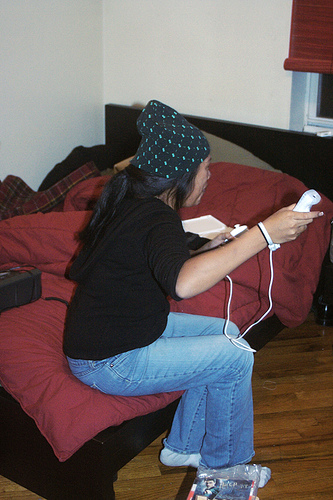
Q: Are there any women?
A: Yes, there is a woman.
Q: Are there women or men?
A: Yes, there is a woman.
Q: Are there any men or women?
A: Yes, there is a woman.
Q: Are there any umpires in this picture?
A: No, there are no umpires.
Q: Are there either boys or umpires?
A: No, there are no umpires or boys.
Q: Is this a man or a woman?
A: This is a woman.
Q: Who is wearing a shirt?
A: The woman is wearing a shirt.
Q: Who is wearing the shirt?
A: The woman is wearing a shirt.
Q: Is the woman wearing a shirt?
A: Yes, the woman is wearing a shirt.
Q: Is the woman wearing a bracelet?
A: No, the woman is wearing a shirt.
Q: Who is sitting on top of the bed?
A: The woman is sitting on top of the bed.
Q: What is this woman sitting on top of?
A: The woman is sitting on top of the bed.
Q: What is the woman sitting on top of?
A: The woman is sitting on top of the bed.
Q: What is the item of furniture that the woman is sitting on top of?
A: The piece of furniture is a bed.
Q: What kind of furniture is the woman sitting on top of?
A: The woman is sitting on top of the bed.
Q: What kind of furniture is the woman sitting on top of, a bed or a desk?
A: The woman is sitting on top of a bed.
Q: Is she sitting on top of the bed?
A: Yes, the woman is sitting on top of the bed.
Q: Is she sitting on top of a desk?
A: No, the woman is sitting on top of the bed.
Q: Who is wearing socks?
A: The woman is wearing socks.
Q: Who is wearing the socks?
A: The woman is wearing socks.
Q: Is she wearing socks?
A: Yes, the woman is wearing socks.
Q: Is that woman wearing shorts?
A: No, the woman is wearing socks.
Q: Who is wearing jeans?
A: The woman is wearing jeans.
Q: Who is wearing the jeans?
A: The woman is wearing jeans.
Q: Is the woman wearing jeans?
A: Yes, the woman is wearing jeans.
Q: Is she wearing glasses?
A: No, the woman is wearing jeans.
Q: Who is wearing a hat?
A: The woman is wearing a hat.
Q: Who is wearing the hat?
A: The woman is wearing a hat.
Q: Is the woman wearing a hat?
A: Yes, the woman is wearing a hat.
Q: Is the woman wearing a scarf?
A: No, the woman is wearing a hat.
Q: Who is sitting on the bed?
A: The woman is sitting on the bed.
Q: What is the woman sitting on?
A: The woman is sitting on the bed.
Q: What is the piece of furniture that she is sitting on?
A: The piece of furniture is a bed.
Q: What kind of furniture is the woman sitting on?
A: The woman is sitting on the bed.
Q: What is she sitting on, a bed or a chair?
A: The woman is sitting on a bed.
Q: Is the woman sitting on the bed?
A: Yes, the woman is sitting on the bed.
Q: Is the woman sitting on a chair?
A: No, the woman is sitting on the bed.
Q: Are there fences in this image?
A: No, there are no fences.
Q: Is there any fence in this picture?
A: No, there are no fences.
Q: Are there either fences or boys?
A: No, there are no fences or boys.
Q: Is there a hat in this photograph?
A: Yes, there is a hat.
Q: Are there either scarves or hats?
A: Yes, there is a hat.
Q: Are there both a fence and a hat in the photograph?
A: No, there is a hat but no fences.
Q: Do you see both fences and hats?
A: No, there is a hat but no fences.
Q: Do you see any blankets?
A: Yes, there is a blanket.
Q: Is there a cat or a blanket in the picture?
A: Yes, there is a blanket.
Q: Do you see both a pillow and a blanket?
A: Yes, there are both a blanket and a pillow.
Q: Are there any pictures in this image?
A: No, there are no pictures.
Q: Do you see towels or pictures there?
A: No, there are no pictures or towels.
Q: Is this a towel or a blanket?
A: This is a blanket.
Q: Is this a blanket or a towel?
A: This is a blanket.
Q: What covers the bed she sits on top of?
A: The blanket covers the bed.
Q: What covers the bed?
A: The blanket covers the bed.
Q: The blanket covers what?
A: The blanket covers the bed.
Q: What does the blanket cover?
A: The blanket covers the bed.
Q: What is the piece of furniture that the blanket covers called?
A: The piece of furniture is a bed.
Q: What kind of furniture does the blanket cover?
A: The blanket covers the bed.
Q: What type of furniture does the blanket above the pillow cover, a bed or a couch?
A: The blanket covers a bed.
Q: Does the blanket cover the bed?
A: Yes, the blanket covers the bed.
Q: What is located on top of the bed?
A: The blanket is on top of the bed.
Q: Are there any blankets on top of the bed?
A: Yes, there is a blanket on top of the bed.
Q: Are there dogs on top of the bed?
A: No, there is a blanket on top of the bed.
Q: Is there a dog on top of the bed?
A: No, there is a blanket on top of the bed.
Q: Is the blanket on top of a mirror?
A: No, the blanket is on top of the bed.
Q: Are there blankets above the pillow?
A: Yes, there is a blanket above the pillow.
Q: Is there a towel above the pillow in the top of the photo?
A: No, there is a blanket above the pillow.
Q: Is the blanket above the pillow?
A: Yes, the blanket is above the pillow.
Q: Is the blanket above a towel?
A: No, the blanket is above the pillow.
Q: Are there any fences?
A: No, there are no fences.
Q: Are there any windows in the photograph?
A: Yes, there is a window.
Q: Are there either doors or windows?
A: Yes, there is a window.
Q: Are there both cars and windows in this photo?
A: No, there is a window but no cars.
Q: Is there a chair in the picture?
A: No, there are no chairs.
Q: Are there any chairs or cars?
A: No, there are no chairs or cars.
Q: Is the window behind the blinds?
A: Yes, the window is behind the blinds.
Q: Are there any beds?
A: Yes, there is a bed.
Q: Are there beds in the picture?
A: Yes, there is a bed.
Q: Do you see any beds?
A: Yes, there is a bed.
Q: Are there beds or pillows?
A: Yes, there is a bed.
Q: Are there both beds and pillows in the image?
A: Yes, there are both a bed and a pillow.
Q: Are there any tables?
A: No, there are no tables.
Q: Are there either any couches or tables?
A: No, there are no tables or couches.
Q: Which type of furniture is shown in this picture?
A: The furniture is a bed.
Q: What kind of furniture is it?
A: The piece of furniture is a bed.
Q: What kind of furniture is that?
A: This is a bed.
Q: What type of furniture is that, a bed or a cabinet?
A: This is a bed.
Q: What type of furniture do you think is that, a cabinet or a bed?
A: This is a bed.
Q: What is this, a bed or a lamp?
A: This is a bed.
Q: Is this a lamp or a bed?
A: This is a bed.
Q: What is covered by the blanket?
A: The bed is covered by the blanket.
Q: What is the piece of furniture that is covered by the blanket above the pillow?
A: The piece of furniture is a bed.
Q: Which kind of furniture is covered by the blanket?
A: The piece of furniture is a bed.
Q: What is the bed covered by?
A: The bed is covered by the blanket.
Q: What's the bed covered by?
A: The bed is covered by the blanket.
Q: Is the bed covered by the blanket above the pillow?
A: Yes, the bed is covered by the blanket.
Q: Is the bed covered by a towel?
A: No, the bed is covered by the blanket.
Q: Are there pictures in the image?
A: No, there are no pictures.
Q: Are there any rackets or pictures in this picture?
A: No, there are no pictures or rackets.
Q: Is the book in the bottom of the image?
A: Yes, the book is in the bottom of the image.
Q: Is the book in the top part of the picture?
A: No, the book is in the bottom of the image.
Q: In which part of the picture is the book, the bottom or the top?
A: The book is in the bottom of the image.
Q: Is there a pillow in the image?
A: Yes, there is a pillow.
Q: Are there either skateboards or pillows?
A: Yes, there is a pillow.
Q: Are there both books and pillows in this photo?
A: Yes, there are both a pillow and a book.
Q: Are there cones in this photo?
A: No, there are no cones.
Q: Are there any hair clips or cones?
A: No, there are no cones or hair clips.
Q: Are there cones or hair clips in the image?
A: No, there are no cones or hair clips.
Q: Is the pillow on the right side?
A: Yes, the pillow is on the right of the image.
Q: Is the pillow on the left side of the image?
A: No, the pillow is on the right of the image.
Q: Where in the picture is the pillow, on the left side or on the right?
A: The pillow is on the right of the image.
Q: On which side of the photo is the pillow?
A: The pillow is on the right of the image.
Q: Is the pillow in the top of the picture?
A: Yes, the pillow is in the top of the image.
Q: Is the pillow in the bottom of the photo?
A: No, the pillow is in the top of the image.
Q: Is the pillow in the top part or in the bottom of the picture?
A: The pillow is in the top of the image.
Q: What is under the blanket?
A: The pillow is under the blanket.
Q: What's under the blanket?
A: The pillow is under the blanket.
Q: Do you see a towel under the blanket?
A: No, there is a pillow under the blanket.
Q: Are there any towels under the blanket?
A: No, there is a pillow under the blanket.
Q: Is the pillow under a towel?
A: No, the pillow is under the blanket.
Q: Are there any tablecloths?
A: No, there are no tablecloths.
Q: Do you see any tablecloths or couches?
A: No, there are no tablecloths or couches.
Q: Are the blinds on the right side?
A: Yes, the blinds are on the right of the image.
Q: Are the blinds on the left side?
A: No, the blinds are on the right of the image.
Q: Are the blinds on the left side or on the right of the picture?
A: The blinds are on the right of the image.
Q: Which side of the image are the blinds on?
A: The blinds are on the right of the image.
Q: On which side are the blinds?
A: The blinds are on the right of the image.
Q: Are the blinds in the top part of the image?
A: Yes, the blinds are in the top of the image.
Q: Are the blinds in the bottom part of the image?
A: No, the blinds are in the top of the image.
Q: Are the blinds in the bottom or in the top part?
A: The blinds are in the top of the image.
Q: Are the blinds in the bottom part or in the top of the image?
A: The blinds are in the top of the image.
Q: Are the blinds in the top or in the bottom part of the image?
A: The blinds are in the top of the image.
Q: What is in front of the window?
A: The blinds are in front of the window.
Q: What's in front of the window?
A: The blinds are in front of the window.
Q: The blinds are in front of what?
A: The blinds are in front of the window.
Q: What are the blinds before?
A: The blinds are in front of the window.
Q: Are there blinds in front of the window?
A: Yes, there are blinds in front of the window.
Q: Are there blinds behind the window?
A: No, the blinds are in front of the window.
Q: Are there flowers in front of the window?
A: No, there are blinds in front of the window.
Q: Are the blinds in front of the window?
A: Yes, the blinds are in front of the window.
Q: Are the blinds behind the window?
A: No, the blinds are in front of the window.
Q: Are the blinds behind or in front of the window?
A: The blinds are in front of the window.